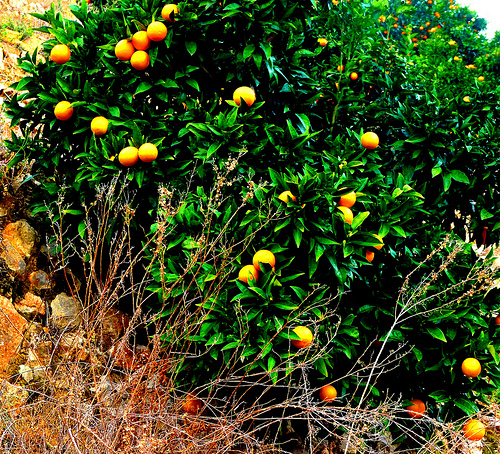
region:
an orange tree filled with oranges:
[1, 0, 498, 451]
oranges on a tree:
[48, 3, 179, 168]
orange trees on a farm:
[0, 2, 498, 439]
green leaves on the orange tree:
[196, 1, 306, 78]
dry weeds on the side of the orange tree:
[1, 167, 188, 452]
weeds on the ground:
[1, 407, 177, 451]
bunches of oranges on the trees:
[13, 1, 498, 441]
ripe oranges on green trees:
[4, 2, 499, 440]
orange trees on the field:
[11, 0, 498, 442]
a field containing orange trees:
[0, 1, 498, 452]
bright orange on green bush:
[153, 13, 178, 44]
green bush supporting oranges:
[63, 13, 498, 326]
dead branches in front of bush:
[26, 331, 335, 453]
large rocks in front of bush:
[1, 222, 99, 452]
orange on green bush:
[251, 247, 281, 273]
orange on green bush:
[455, 352, 487, 385]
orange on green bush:
[457, 417, 497, 442]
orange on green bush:
[131, 23, 156, 55]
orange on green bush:
[242, 260, 263, 290]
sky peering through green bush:
[466, 6, 495, 44]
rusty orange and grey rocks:
[2, 216, 251, 451]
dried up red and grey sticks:
[10, 165, 495, 452]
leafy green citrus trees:
[7, 1, 499, 441]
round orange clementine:
[100, 5, 168, 75]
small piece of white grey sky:
[453, 0, 498, 42]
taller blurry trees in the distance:
[360, 0, 490, 45]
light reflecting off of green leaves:
[261, 42, 453, 171]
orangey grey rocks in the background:
[2, 0, 77, 145]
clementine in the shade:
[395, 390, 427, 424]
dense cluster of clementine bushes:
[1, 2, 498, 431]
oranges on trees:
[69, 27, 444, 402]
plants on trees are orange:
[14, 6, 223, 303]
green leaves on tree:
[20, 23, 320, 327]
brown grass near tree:
[0, 293, 178, 406]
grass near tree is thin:
[39, 281, 183, 446]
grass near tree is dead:
[52, 216, 223, 451]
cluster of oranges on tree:
[80, 13, 176, 92]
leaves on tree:
[144, 6, 491, 281]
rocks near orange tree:
[9, 225, 92, 335]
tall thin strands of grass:
[328, 282, 465, 445]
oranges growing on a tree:
[35, 17, 403, 379]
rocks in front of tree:
[6, 222, 111, 419]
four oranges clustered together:
[107, 18, 181, 78]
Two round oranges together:
[111, 144, 177, 189]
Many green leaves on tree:
[59, 20, 428, 372]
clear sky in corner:
[470, 1, 499, 32]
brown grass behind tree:
[6, 3, 95, 141]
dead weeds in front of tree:
[41, 193, 362, 453]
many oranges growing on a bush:
[41, 21, 461, 413]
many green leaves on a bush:
[41, 16, 498, 315]